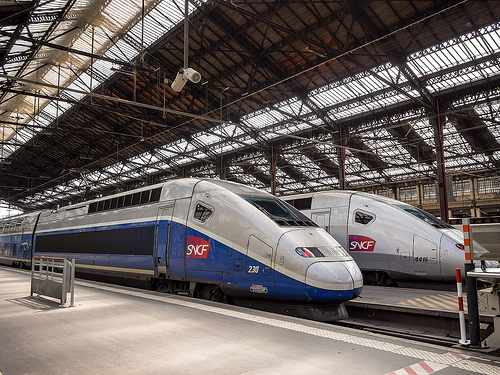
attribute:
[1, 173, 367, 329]
train — passenger, high-speed, gray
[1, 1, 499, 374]
station — train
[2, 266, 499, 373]
platform — area, cement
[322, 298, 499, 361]
track — train, metal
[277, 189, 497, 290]
train — gray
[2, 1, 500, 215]
roof — high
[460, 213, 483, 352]
rail — warning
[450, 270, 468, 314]
stripes — red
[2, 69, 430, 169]
beam — metal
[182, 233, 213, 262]
sign — sncf